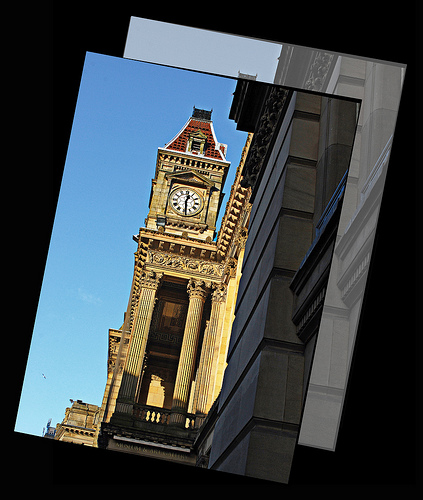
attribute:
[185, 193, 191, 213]
hand — hour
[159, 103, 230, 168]
roof — tile, orange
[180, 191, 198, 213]
hands — black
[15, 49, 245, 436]
sky — clear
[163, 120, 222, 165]
roof — red , shingle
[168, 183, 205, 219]
clock — large, outdoor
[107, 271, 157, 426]
pillar — support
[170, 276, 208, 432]
pillar — support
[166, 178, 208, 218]
clock — circular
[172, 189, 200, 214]
time — 12:30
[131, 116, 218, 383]
building — old, stone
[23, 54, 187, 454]
sky — clear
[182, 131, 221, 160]
window — small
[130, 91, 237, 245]
clock tower — pictured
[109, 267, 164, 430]
column — square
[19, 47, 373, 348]
photo — tilted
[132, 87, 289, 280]
decorative architecture — pictured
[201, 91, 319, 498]
wall — grey, stone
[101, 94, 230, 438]
tower — clock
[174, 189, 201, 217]
clock face — pictured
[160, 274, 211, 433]
column — round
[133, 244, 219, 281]
sidework — ornate